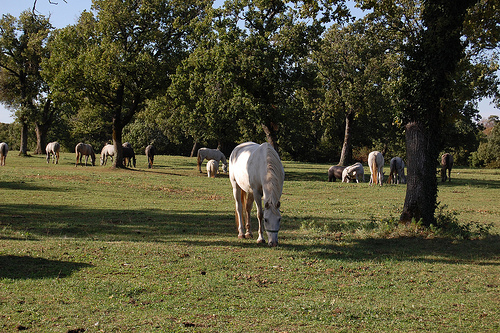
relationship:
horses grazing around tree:
[326, 148, 406, 184] [317, 4, 498, 224]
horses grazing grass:
[229, 140, 284, 245] [53, 247, 483, 324]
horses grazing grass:
[366, 147, 386, 180] [53, 247, 483, 324]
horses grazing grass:
[338, 161, 367, 181] [53, 247, 483, 324]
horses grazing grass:
[193, 140, 230, 171] [53, 247, 483, 324]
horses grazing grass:
[72, 140, 97, 165] [53, 247, 483, 324]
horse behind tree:
[101, 142, 116, 164] [37, 0, 214, 167]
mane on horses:
[264, 148, 283, 209] [228, 140, 286, 247]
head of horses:
[260, 201, 281, 246] [228, 140, 286, 247]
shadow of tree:
[325, 211, 495, 272] [381, 0, 498, 220]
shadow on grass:
[325, 211, 495, 272] [0, 144, 498, 329]